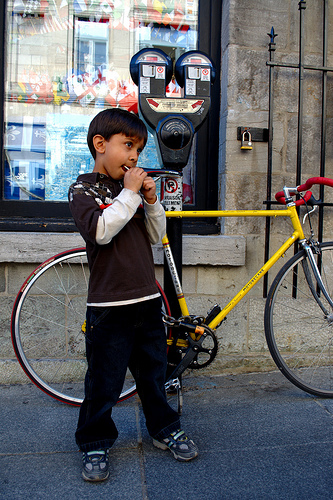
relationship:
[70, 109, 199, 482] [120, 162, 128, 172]
boy has a sucker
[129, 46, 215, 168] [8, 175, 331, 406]
parking meter behind bike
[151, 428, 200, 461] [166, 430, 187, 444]
shoe has velcro strap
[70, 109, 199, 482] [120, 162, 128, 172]
boy holds a sucker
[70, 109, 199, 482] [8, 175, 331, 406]
boy in front of bike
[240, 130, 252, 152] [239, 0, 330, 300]
padlock on gate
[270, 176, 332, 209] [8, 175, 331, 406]
handles on bike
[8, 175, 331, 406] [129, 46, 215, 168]
bike leaning against parking meter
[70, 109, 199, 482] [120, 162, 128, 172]
boy enjoying a sucker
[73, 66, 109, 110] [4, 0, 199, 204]
flag in window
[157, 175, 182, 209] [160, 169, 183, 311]
no parking sticker on pole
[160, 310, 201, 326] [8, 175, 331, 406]
security chain on bike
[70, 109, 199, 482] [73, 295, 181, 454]
boy wearing pants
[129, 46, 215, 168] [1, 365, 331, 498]
parking meter on sidewalk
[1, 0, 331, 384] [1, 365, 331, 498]
buiding by sidewalk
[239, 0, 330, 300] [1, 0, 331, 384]
gate mounted to buiding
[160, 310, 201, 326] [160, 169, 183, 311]
security chain tied to pole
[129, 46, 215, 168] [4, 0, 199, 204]
parking meter by window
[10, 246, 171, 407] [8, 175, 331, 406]
wheel of bike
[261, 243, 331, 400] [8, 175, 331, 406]
wheel of bike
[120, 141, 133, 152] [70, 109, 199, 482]
eye of boy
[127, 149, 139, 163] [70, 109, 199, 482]
nose of boy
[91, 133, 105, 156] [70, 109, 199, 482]
ear of boy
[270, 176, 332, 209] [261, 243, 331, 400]
handles are above wheel